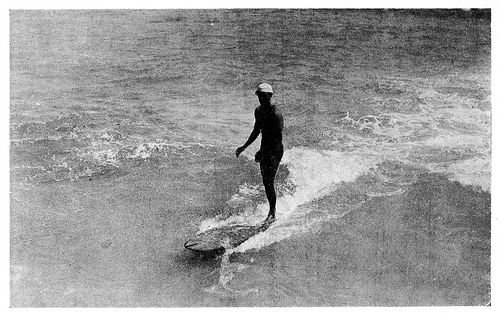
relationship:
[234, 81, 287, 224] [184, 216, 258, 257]
man on surfboard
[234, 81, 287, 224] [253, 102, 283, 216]
man wearing swim gear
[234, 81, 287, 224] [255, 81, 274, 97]
man wearing cap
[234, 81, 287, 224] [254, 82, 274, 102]
man has head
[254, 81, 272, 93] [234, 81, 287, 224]
cap on man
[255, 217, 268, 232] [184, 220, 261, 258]
feet on surfboard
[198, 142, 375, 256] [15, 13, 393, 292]
wave in water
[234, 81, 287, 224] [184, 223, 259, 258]
man in surfboard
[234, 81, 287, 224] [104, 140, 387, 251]
man riding wave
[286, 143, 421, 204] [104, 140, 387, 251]
foam from wave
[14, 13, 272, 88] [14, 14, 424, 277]
ripples in water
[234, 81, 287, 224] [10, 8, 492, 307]
man surfing in ocean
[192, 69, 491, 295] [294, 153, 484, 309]
wave make a triangle shape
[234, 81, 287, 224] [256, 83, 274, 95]
man with cap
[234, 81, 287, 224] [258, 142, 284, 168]
man wearing shorts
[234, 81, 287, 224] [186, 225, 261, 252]
man on surfboard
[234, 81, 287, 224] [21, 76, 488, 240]
man on wave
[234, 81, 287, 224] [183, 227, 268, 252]
man on surfboard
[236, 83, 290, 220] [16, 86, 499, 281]
man riding wave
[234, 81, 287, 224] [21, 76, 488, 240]
man riding wave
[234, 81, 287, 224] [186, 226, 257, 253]
man riding surfboard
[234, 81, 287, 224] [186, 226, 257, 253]
man on surfboard